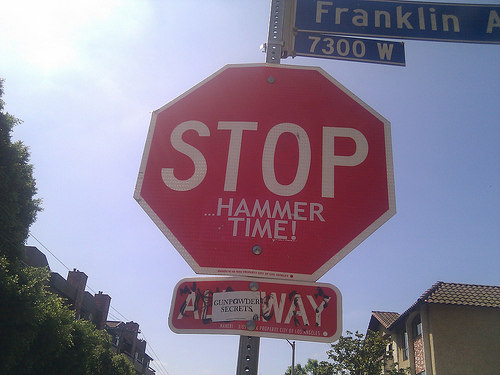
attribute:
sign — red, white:
[131, 62, 398, 282]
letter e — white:
[293, 200, 308, 220]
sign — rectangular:
[175, 277, 342, 344]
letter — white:
[210, 197, 234, 219]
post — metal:
[225, 311, 291, 372]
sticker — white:
[208, 288, 263, 319]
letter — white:
[217, 117, 252, 193]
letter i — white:
[243, 218, 248, 240]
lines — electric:
[27, 232, 152, 338]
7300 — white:
[296, 33, 404, 66]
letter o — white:
[266, 113, 318, 204]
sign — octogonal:
[96, 61, 417, 281]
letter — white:
[320, 124, 370, 201]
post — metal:
[233, 336, 263, 373]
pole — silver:
[242, 325, 263, 371]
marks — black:
[182, 270, 333, 330]